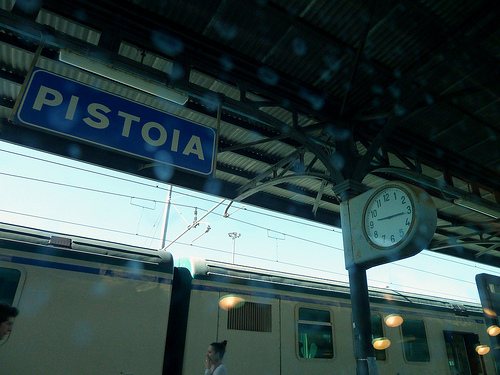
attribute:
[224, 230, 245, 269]
light — silver, metal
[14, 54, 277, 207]
sign — large, blue, white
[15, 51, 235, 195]
sign — blue, metal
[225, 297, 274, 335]
vent —  Outer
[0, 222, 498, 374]
train —  subway's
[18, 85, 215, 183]
sign — blue, white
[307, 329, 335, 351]
face —  Man's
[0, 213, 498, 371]
subway train —  subway's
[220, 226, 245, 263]
light —  tall,  for parking lot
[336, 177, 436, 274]
clock — round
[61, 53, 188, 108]
light — fluorescent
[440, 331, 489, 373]
doors — open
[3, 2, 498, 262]
roof rafters — large, metal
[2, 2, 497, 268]
overpass — metal, large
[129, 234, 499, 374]
train — white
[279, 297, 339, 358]
window —  train's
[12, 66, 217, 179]
sign — metal, blue, in foreign language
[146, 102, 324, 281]
window —  large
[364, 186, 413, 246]
clockface — white, metal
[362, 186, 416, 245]
clock — large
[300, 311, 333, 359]
window —  train's